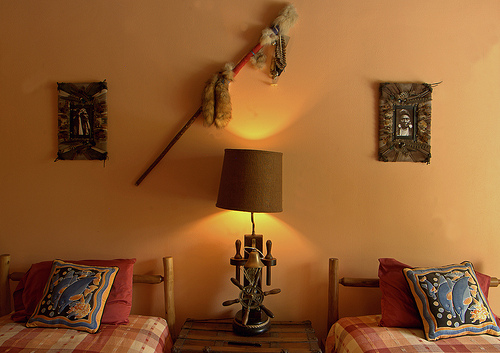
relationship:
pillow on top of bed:
[21, 251, 122, 337] [3, 246, 177, 353]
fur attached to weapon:
[199, 60, 239, 132] [125, 3, 302, 190]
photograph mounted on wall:
[53, 76, 109, 168] [0, 2, 498, 322]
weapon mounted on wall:
[125, 3, 302, 190] [0, 2, 498, 322]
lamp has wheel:
[214, 144, 294, 339] [219, 267, 287, 329]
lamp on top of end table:
[214, 144, 294, 339] [169, 308, 322, 353]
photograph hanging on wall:
[53, 76, 109, 168] [0, 2, 498, 322]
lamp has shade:
[214, 144, 294, 339] [207, 144, 289, 220]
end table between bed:
[169, 308, 322, 353] [3, 246, 177, 353]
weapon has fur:
[125, 3, 302, 190] [199, 60, 239, 132]